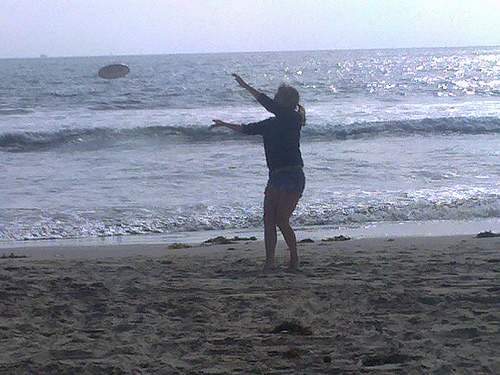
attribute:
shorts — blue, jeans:
[267, 162, 304, 194]